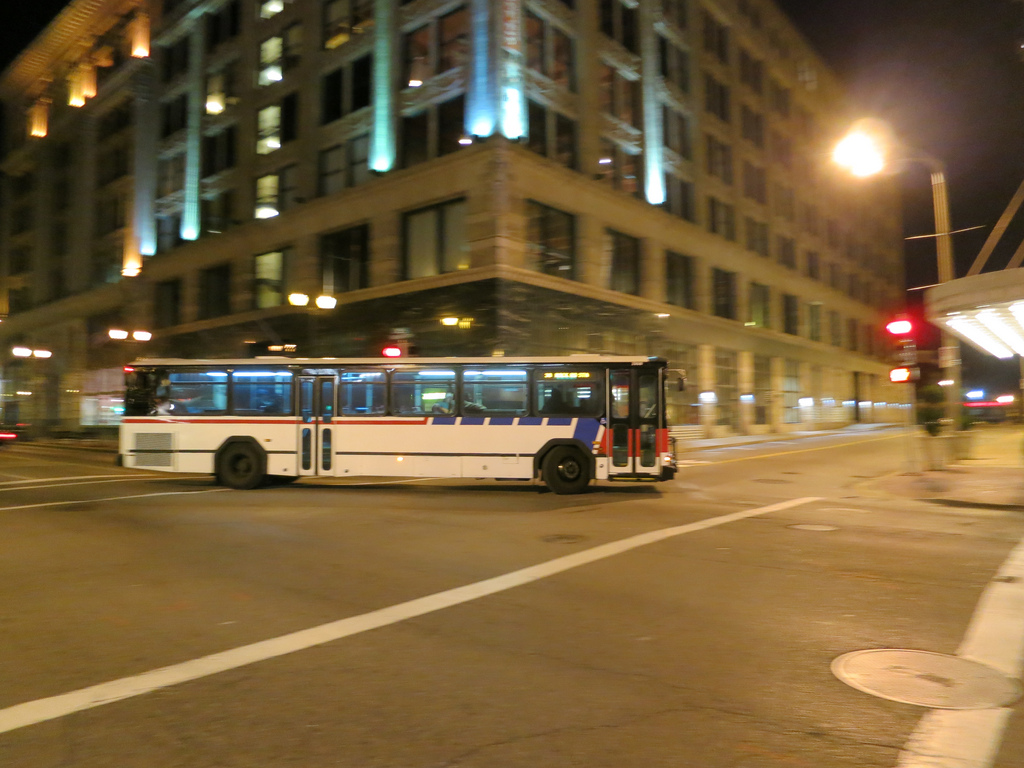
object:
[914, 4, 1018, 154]
dark sky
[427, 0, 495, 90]
window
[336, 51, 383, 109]
window 2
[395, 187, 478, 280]
window 3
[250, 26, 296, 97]
window 4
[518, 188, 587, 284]
window 5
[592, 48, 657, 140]
window 6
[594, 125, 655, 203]
window 7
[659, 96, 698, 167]
window 8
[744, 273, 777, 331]
window 9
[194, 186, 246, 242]
window 10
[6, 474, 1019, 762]
crosswalk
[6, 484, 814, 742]
white line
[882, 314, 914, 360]
red light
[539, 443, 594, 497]
front wheel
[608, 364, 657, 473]
door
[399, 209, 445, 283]
window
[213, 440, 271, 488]
tire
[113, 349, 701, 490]
bus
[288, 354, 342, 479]
door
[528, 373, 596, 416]
window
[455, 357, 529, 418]
window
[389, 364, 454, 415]
window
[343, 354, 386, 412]
window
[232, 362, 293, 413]
window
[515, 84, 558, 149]
window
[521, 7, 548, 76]
window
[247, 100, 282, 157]
window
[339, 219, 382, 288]
window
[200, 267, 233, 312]
window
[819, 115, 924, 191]
street light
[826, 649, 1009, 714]
man hole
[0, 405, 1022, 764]
street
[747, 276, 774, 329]
window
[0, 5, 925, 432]
building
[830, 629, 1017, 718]
top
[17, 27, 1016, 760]
city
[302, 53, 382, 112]
window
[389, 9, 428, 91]
window